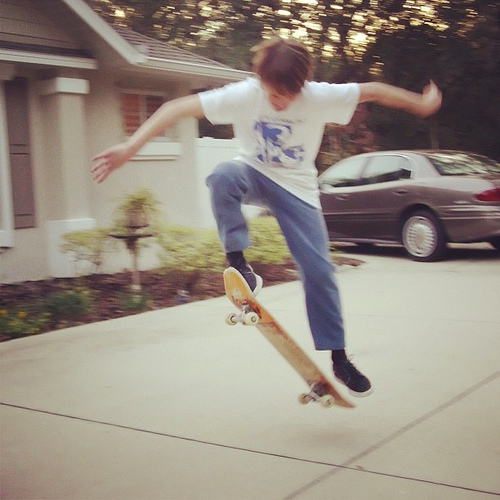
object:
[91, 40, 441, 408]
skateboarder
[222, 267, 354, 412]
skateboard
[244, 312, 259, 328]
wheels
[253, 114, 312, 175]
blue art print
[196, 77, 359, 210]
white t-shirt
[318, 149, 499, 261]
grey car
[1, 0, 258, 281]
house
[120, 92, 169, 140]
jalousie type window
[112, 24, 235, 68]
cement or clay roof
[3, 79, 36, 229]
wood window trim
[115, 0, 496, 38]
sunlight is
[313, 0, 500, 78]
trees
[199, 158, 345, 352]
blue jeans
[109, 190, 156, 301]
decorative planter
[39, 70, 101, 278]
concrete columns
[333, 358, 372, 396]
skateboard shoes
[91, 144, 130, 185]
hands for balance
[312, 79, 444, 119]
hands for balance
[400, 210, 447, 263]
wheels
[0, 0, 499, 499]
an action photo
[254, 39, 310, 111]
head protection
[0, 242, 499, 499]
driveway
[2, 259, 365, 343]
front garden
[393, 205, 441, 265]
silver wheels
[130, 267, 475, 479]
sidewalk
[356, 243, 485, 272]
driveway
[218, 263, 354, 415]
board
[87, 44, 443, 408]
boy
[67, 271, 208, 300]
dirt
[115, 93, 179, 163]
window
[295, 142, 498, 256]
car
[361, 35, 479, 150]
treess